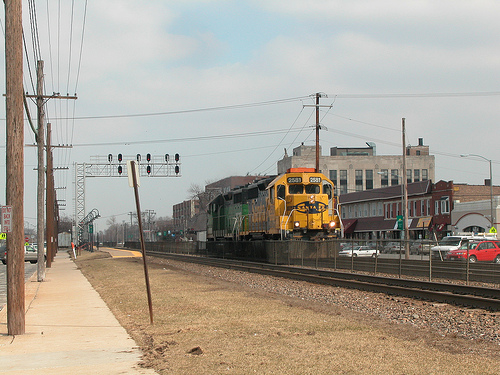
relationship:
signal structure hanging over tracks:
[61, 137, 199, 191] [114, 226, 495, 314]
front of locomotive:
[269, 163, 346, 261] [248, 172, 341, 259]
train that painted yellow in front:
[207, 174, 342, 263] [269, 163, 346, 261]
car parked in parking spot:
[446, 239, 498, 263] [433, 250, 493, 269]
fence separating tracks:
[334, 239, 499, 283] [139, 234, 496, 303]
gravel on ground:
[332, 280, 367, 307] [90, 242, 498, 372]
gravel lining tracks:
[332, 280, 367, 307] [128, 232, 493, 313]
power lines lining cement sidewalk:
[23, 58, 74, 283] [0, 248, 160, 374]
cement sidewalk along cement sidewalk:
[47, 275, 85, 338] [0, 248, 160, 374]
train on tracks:
[207, 174, 342, 263] [122, 237, 498, 307]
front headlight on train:
[286, 216, 307, 229] [169, 164, 351, 269]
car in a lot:
[446, 239, 498, 263] [365, 242, 498, 272]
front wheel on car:
[460, 245, 480, 267] [446, 239, 498, 263]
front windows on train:
[285, 180, 326, 192] [191, 163, 335, 247]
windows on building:
[349, 164, 384, 201] [270, 148, 498, 258]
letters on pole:
[0, 204, 12, 236] [6, 0, 27, 333]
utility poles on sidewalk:
[12, 43, 90, 286] [0, 237, 144, 370]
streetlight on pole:
[455, 150, 468, 162] [465, 155, 497, 264]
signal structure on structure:
[102, 152, 183, 177] [75, 140, 165, 194]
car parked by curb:
[440, 219, 492, 272] [436, 259, 479, 284]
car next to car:
[465, 228, 487, 278] [428, 236, 492, 260]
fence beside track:
[289, 256, 391, 294] [316, 258, 499, 312]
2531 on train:
[280, 155, 334, 195] [244, 158, 346, 264]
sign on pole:
[388, 214, 428, 238] [374, 139, 430, 286]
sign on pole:
[2, 200, 56, 264] [2, 229, 38, 328]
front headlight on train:
[291, 220, 300, 227] [210, 145, 388, 305]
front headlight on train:
[291, 220, 300, 227] [155, 149, 339, 281]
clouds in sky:
[94, 12, 174, 94] [137, 9, 267, 80]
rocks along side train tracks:
[313, 284, 382, 324] [331, 257, 411, 304]